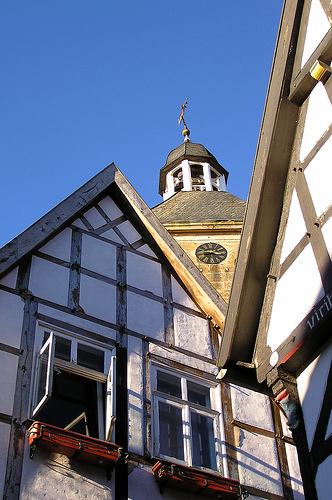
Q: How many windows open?
A: 1.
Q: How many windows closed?
A: 1.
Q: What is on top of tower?
A: Weather vane.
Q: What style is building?
A: Tudor.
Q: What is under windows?
A: Red flower boxes.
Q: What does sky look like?
A: Bright blue cloudless.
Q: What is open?
A: Window on building.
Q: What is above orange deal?
A: Open window.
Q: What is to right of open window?
A: Shut window.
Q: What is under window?
A: Red planter box.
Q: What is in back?
A: White and brown building.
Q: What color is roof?
A: Brown.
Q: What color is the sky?
A: Bright blue.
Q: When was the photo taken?
A: Day time.